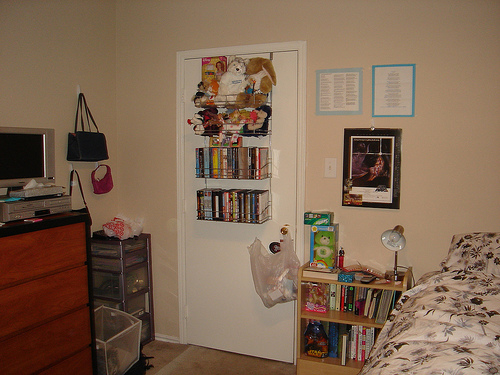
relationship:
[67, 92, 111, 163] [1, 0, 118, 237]
purse on wall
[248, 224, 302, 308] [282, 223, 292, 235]
bag on door handle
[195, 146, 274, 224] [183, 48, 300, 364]
book shelves on door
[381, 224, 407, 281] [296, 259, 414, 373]
lamp on book shelf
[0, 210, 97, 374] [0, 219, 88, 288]
dresser has drawer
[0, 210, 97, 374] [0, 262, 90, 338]
dresser has drawer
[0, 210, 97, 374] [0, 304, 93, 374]
dresser has drawer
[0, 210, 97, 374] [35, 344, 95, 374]
dresser has drawer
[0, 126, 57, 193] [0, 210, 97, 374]
computer on dresser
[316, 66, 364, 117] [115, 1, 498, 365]
paper on wall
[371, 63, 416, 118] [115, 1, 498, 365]
paper on wall